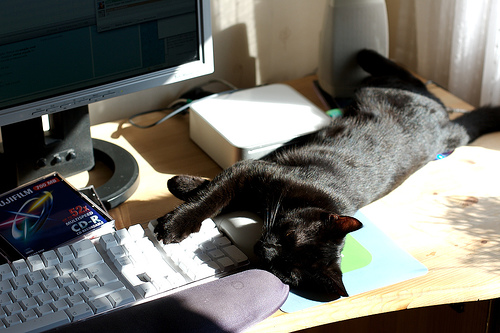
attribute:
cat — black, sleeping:
[285, 115, 407, 212]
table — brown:
[137, 138, 198, 176]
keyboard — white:
[23, 229, 172, 320]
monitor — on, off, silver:
[11, 10, 205, 82]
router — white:
[202, 92, 299, 147]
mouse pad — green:
[352, 238, 418, 290]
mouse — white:
[224, 215, 257, 245]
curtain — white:
[413, 8, 494, 77]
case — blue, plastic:
[12, 190, 100, 240]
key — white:
[59, 274, 69, 287]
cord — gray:
[157, 116, 174, 124]